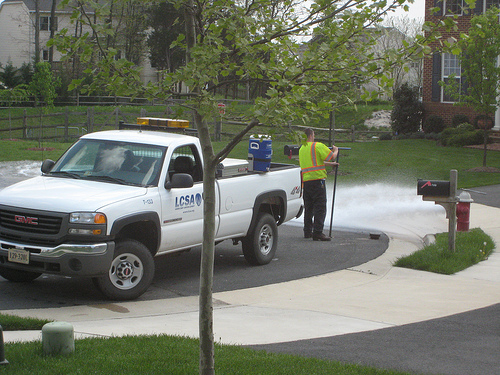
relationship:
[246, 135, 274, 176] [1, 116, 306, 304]
cooler in back of truck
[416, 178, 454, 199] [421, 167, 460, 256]
mailbox on top of post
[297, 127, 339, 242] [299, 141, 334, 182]
man in shirt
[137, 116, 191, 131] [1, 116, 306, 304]
lights are on top of truck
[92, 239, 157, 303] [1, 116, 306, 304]
tire on truck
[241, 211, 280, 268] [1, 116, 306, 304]
tire on truck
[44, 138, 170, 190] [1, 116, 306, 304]
windshield on truck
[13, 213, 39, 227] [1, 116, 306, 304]
letters on front of truck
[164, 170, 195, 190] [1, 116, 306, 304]
left mirror on truck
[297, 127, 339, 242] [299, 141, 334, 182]
man wearing shirt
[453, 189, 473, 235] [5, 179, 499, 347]
hydrant on sidewalk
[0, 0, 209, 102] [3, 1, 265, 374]
building on left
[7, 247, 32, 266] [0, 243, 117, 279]
plate in front of bumper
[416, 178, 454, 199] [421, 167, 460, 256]
mailbox on post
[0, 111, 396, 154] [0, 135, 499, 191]
fence lines yard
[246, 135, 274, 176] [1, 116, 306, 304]
cooler on truck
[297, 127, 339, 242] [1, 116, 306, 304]
man has truck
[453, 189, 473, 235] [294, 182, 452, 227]
hydrant spewing water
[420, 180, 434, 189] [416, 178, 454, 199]
flag on mailbox